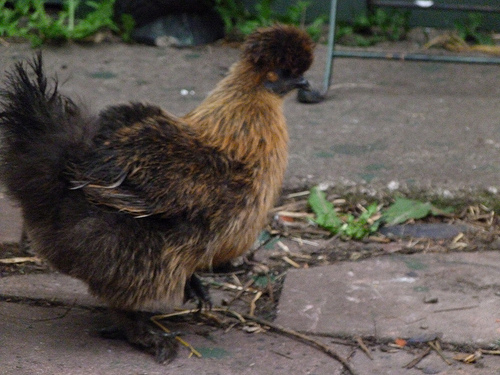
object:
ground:
[1, 35, 498, 374]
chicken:
[2, 23, 314, 333]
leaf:
[309, 187, 381, 242]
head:
[239, 28, 311, 98]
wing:
[78, 117, 238, 218]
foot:
[102, 302, 180, 361]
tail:
[1, 53, 87, 237]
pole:
[323, 1, 341, 94]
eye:
[280, 69, 291, 80]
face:
[275, 63, 309, 95]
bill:
[292, 78, 309, 90]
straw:
[153, 300, 254, 354]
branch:
[233, 307, 353, 370]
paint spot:
[184, 341, 236, 359]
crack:
[3, 285, 498, 360]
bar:
[333, 44, 498, 69]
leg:
[84, 236, 181, 361]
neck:
[188, 70, 295, 160]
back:
[74, 97, 202, 170]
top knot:
[253, 22, 313, 69]